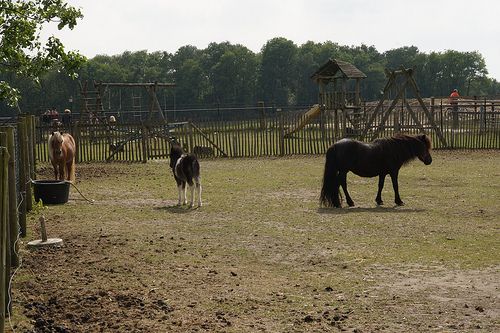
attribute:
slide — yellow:
[266, 89, 329, 136]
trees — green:
[63, 34, 492, 115]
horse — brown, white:
[41, 113, 82, 207]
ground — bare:
[165, 233, 272, 302]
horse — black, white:
[170, 144, 211, 216]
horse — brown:
[321, 105, 457, 208]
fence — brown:
[203, 91, 344, 163]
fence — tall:
[205, 111, 374, 167]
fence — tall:
[199, 104, 393, 145]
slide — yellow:
[268, 76, 335, 150]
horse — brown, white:
[150, 142, 244, 207]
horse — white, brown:
[46, 113, 102, 207]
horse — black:
[301, 127, 466, 216]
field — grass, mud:
[50, 169, 472, 327]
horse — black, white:
[168, 142, 238, 228]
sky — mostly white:
[85, 7, 478, 57]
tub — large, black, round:
[38, 168, 81, 215]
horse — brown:
[30, 120, 99, 203]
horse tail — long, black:
[315, 130, 346, 214]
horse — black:
[320, 127, 420, 218]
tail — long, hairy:
[309, 142, 343, 214]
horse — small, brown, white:
[139, 136, 222, 208]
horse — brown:
[46, 114, 85, 197]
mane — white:
[34, 122, 62, 152]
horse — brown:
[157, 134, 216, 214]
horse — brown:
[312, 117, 447, 234]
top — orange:
[447, 92, 457, 105]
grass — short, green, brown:
[286, 261, 351, 311]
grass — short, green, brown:
[431, 248, 489, 287]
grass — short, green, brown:
[222, 158, 332, 232]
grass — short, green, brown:
[115, 210, 226, 300]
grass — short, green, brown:
[85, 284, 151, 322]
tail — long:
[314, 134, 348, 225]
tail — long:
[313, 140, 345, 205]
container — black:
[25, 172, 76, 203]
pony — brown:
[39, 125, 99, 201]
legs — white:
[186, 180, 205, 210]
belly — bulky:
[349, 161, 392, 184]